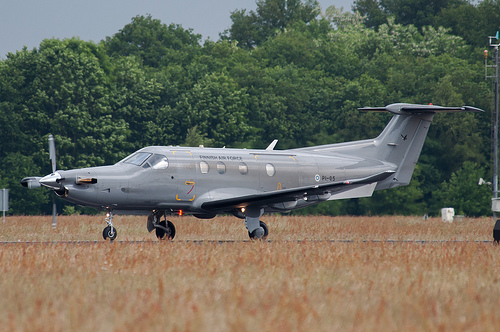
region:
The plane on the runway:
[18, 97, 483, 252]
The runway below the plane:
[7, 235, 498, 245]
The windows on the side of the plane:
[194, 156, 279, 178]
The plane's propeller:
[20, 131, 99, 227]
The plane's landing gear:
[97, 210, 274, 243]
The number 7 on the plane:
[180, 178, 196, 197]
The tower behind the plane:
[477, 26, 499, 215]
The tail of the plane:
[355, 99, 486, 191]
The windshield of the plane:
[125, 148, 167, 172]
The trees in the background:
[1, 0, 498, 220]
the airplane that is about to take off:
[31, 86, 493, 227]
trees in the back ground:
[132, 21, 409, 134]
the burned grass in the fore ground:
[151, 253, 236, 325]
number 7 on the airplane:
[164, 170, 237, 200]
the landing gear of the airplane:
[137, 213, 326, 240]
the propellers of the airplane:
[30, 136, 110, 233]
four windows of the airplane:
[176, 154, 321, 181]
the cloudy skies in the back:
[60, 13, 115, 35]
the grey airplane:
[41, 110, 448, 262]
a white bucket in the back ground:
[431, 196, 454, 232]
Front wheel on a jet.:
[99, 221, 118, 242]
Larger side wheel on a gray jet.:
[152, 218, 177, 241]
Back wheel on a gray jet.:
[244, 220, 270, 238]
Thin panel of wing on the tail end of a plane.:
[357, 102, 487, 115]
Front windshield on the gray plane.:
[120, 149, 167, 169]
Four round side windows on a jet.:
[195, 159, 275, 174]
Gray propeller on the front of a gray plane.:
[17, 131, 67, 230]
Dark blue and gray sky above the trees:
[0, 0, 236, 60]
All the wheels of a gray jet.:
[97, 221, 270, 242]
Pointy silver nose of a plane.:
[37, 170, 60, 190]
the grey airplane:
[33, 121, 479, 243]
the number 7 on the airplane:
[159, 172, 226, 207]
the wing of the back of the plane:
[334, 93, 434, 163]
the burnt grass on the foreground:
[176, 276, 227, 306]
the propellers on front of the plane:
[26, 136, 86, 202]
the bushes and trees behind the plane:
[106, 48, 262, 122]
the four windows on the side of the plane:
[196, 156, 329, 181]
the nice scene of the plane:
[28, 13, 70, 243]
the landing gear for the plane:
[83, 205, 370, 274]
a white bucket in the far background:
[444, 198, 477, 228]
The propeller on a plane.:
[36, 125, 66, 245]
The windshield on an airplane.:
[115, 140, 170, 171]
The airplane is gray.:
[20, 90, 470, 251]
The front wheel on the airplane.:
[88, 202, 123, 248]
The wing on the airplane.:
[191, 161, 401, 224]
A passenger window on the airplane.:
[260, 156, 282, 177]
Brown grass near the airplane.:
[22, 241, 470, 327]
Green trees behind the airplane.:
[95, 42, 337, 117]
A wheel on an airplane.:
[240, 208, 271, 255]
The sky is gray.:
[17, 5, 105, 31]